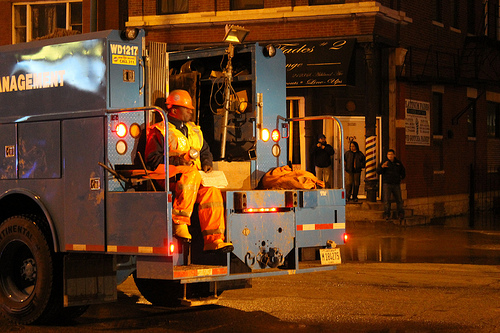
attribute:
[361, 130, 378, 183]
pole — striped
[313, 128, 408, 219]
people — three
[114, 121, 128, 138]
light — red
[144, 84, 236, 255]
man — long-sleeve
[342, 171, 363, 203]
jeans — blue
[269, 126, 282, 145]
light — on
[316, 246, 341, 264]
license plate — White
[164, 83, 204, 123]
hat — orange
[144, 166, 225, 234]
pants — orange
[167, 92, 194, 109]
hard hat — orange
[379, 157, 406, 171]
coat — black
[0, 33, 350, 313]
truck — work truck, light blue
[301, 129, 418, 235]
people — 3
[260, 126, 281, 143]
lights — on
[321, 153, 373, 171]
coat — dark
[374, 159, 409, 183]
coat — black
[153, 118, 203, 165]
vest — orange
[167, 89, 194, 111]
hardhat — orange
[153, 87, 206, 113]
hat — orange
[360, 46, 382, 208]
pole — red, white, blue, barber pole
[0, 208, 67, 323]
tire — back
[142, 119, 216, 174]
shirt — dark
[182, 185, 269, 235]
pants — orange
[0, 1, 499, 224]
building — brick